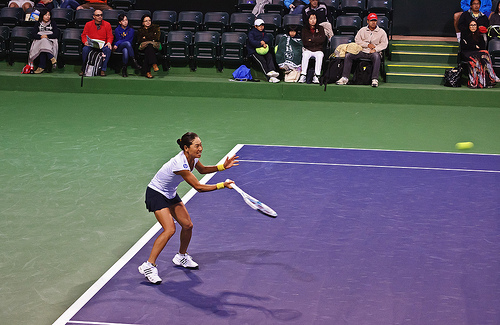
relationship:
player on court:
[136, 130, 239, 286] [2, 65, 499, 325]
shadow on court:
[141, 265, 302, 324] [2, 65, 499, 325]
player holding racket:
[136, 130, 239, 286] [227, 180, 280, 224]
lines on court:
[237, 141, 500, 157] [2, 65, 499, 325]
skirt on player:
[144, 185, 185, 212] [136, 130, 239, 286]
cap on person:
[368, 12, 378, 22] [335, 12, 389, 88]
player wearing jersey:
[136, 130, 239, 286] [147, 149, 200, 201]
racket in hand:
[227, 180, 280, 224] [221, 177, 235, 192]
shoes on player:
[136, 261, 161, 284] [136, 130, 239, 286]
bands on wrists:
[216, 164, 225, 172] [218, 162, 228, 174]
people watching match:
[10, 8, 149, 73] [75, 88, 443, 322]